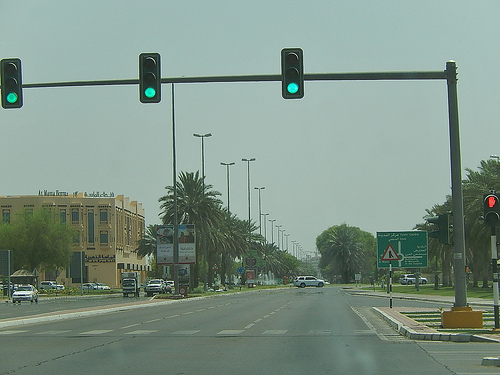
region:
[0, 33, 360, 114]
Traffic lights hanging over street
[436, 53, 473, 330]
Pole holding traffic lights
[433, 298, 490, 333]
Yellow base of pole holding traffic lights.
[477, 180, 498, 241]
crosswalk signal showing don't walk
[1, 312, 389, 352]
crosswalk on street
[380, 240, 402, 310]
yield sign on street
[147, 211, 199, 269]
signs on street median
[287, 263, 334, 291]
white suv crossing street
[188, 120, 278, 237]
street lights on median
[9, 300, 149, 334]
median between two streets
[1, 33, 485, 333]
green light, in triplicate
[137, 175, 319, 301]
umpteen palm trees standing in a line down the center divider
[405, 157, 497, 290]
a smaller number of palm trees amassed en masse over by the side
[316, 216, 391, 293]
palm trees, again, exact number unknown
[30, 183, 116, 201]
shop names in dark metal letters along roof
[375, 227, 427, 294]
large street sign written in @ least two languages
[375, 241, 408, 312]
road merges, in a triangle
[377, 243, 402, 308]
white triangle road sign w/ red border on black+white striped pole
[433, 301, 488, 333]
traffic signal's yellow concrete base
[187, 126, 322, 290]
streetlights whose dual lamps look like propellors stretching far beyond where the eye can see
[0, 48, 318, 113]
TRAFFIC LIGHTS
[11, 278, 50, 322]
THE CAR IS WHITE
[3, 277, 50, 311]
THE CAR IS PARKED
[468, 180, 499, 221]
DO NOT CROSS SIGN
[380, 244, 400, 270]
THE SIGN IS A TRIANGLE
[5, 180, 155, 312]
THE BUILDING IS BROWN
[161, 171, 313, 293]
THE TREES ARE PALMS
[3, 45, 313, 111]
THE TRAFFIC LIGHTS ARE GREEN FOR GO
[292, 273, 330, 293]
THE SUV IS WHITE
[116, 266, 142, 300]
THE TRUCK IS ON THE STREET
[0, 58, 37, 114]
the light is green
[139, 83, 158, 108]
the light is green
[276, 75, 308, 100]
the light is green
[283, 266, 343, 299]
the car is white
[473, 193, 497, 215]
the light syas stop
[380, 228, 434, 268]
the sign post is blue in color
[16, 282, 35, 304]
the car is white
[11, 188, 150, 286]
the building is brown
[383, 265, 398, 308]
the post is black and white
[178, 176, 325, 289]
the lights are in a row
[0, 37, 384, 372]
three green lights on pole over road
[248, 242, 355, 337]
white vehicle crossing street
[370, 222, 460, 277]
green and white sign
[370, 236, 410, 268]
red, white, and black sign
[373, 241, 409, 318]
black and white striped post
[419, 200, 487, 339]
traffic light on pole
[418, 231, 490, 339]
pole in yellow base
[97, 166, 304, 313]
palm trees in median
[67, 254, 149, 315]
white truck on road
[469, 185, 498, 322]
red traffic light on black and white pole